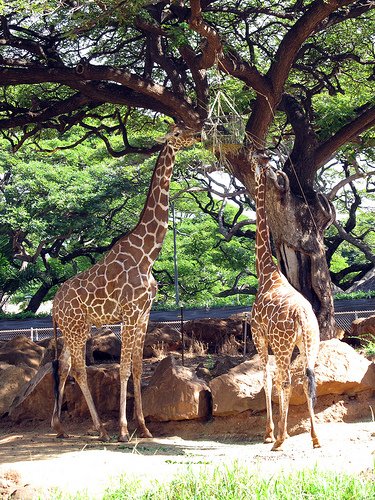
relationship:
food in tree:
[187, 79, 248, 175] [4, 4, 375, 347]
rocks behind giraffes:
[0, 313, 374, 432] [41, 123, 328, 452]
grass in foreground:
[33, 456, 374, 497] [0, 396, 373, 497]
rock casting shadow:
[204, 336, 369, 454] [148, 418, 339, 446]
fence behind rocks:
[0, 307, 374, 352] [0, 313, 374, 432]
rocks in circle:
[0, 313, 374, 432] [5, 329, 374, 458]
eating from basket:
[159, 102, 278, 192] [204, 85, 241, 160]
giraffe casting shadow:
[38, 118, 204, 443] [3, 431, 206, 462]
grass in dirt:
[33, 456, 374, 497] [4, 417, 373, 485]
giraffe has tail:
[38, 118, 204, 443] [47, 304, 64, 405]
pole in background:
[168, 197, 191, 307] [1, 146, 371, 310]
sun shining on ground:
[130, 339, 374, 458] [0, 343, 373, 498]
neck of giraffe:
[95, 147, 179, 266] [51, 118, 201, 452]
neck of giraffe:
[254, 176, 293, 287] [249, 147, 321, 451]